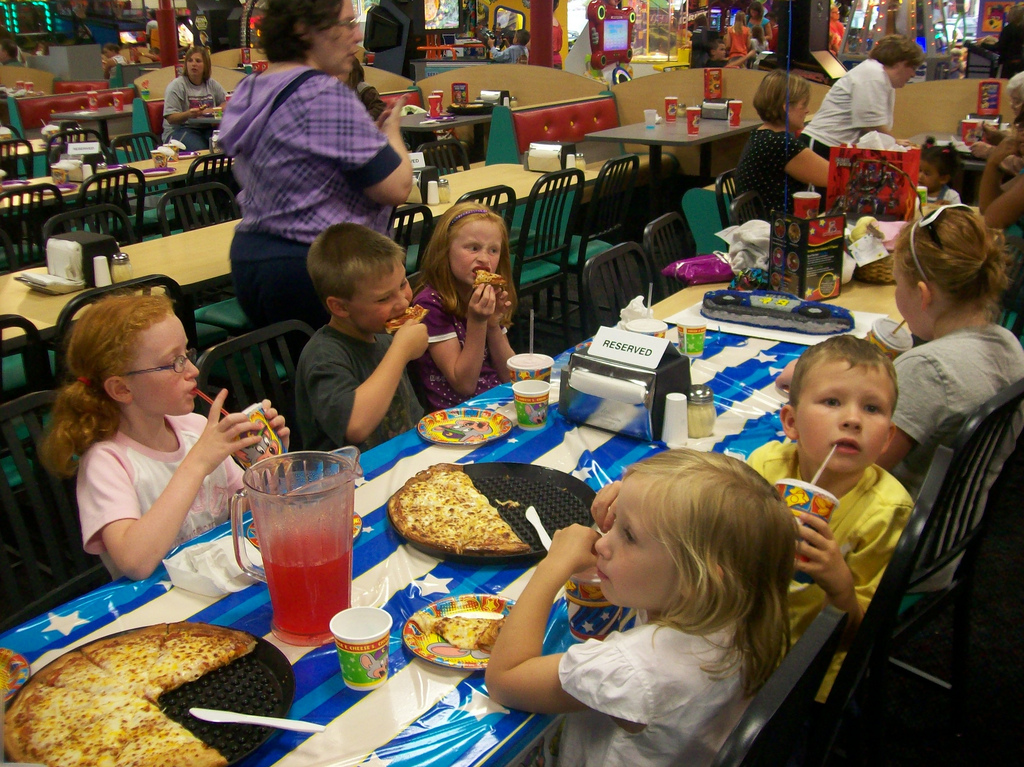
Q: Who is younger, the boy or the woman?
A: The boy is younger than the woman.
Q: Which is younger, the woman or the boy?
A: The boy is younger than the woman.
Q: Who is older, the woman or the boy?
A: The woman is older than the boy.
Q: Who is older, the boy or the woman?
A: The woman is older than the boy.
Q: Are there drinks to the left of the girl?
A: Yes, there is a drink to the left of the girl.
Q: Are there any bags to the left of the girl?
A: No, there is a drink to the left of the girl.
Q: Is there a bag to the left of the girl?
A: No, there is a drink to the left of the girl.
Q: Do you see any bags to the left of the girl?
A: No, there is a drink to the left of the girl.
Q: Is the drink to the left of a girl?
A: Yes, the drink is to the left of a girl.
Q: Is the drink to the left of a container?
A: No, the drink is to the left of a girl.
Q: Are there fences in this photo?
A: No, there are no fences.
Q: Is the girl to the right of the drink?
A: Yes, the girl is to the right of the drink.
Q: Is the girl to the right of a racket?
A: No, the girl is to the right of the drink.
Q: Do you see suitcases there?
A: No, there are no suitcases.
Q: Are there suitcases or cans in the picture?
A: No, there are no suitcases or cans.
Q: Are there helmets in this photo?
A: No, there are no helmets.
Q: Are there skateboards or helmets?
A: No, there are no helmets or skateboards.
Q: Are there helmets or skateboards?
A: No, there are no helmets or skateboards.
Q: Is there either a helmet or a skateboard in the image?
A: No, there are no helmets or skateboards.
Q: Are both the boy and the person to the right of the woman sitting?
A: Yes, both the boy and the person are sitting.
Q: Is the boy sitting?
A: Yes, the boy is sitting.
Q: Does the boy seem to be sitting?
A: Yes, the boy is sitting.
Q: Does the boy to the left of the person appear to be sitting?
A: Yes, the boy is sitting.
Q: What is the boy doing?
A: The boy is sitting.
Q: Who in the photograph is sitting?
A: The boy is sitting.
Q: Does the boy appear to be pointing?
A: No, the boy is sitting.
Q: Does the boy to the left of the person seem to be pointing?
A: No, the boy is sitting.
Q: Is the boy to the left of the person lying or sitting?
A: The boy is sitting.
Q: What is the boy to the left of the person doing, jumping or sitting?
A: The boy is sitting.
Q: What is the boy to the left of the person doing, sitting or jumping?
A: The boy is sitting.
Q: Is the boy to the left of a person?
A: Yes, the boy is to the left of a person.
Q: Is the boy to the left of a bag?
A: No, the boy is to the left of a person.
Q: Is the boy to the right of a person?
A: No, the boy is to the left of a person.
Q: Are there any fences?
A: No, there are no fences.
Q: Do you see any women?
A: Yes, there is a woman.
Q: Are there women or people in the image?
A: Yes, there is a woman.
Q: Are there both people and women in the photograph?
A: Yes, there are both a woman and a person.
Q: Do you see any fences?
A: No, there are no fences.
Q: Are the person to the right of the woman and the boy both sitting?
A: Yes, both the person and the boy are sitting.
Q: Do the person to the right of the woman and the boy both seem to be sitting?
A: Yes, both the person and the boy are sitting.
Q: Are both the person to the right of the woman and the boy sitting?
A: Yes, both the person and the boy are sitting.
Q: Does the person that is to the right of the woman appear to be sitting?
A: Yes, the person is sitting.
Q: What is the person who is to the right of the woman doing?
A: The person is sitting.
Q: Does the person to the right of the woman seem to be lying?
A: No, the person is sitting.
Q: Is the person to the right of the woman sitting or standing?
A: The person is sitting.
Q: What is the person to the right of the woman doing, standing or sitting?
A: The person is sitting.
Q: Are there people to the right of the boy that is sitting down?
A: Yes, there is a person to the right of the boy.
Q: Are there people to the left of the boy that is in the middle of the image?
A: No, the person is to the right of the boy.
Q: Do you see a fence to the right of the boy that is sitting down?
A: No, there is a person to the right of the boy.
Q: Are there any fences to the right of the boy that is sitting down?
A: No, there is a person to the right of the boy.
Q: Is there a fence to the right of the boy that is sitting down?
A: No, there is a person to the right of the boy.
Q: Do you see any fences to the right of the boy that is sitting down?
A: No, there is a person to the right of the boy.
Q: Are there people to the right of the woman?
A: Yes, there is a person to the right of the woman.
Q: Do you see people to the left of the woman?
A: No, the person is to the right of the woman.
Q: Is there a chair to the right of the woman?
A: No, there is a person to the right of the woman.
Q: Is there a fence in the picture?
A: No, there are no fences.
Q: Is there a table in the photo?
A: Yes, there is a table.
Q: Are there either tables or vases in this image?
A: Yes, there is a table.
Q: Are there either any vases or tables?
A: Yes, there is a table.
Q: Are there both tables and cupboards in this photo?
A: No, there is a table but no cupboards.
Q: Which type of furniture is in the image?
A: The furniture is a table.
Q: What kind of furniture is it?
A: The piece of furniture is a table.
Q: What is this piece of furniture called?
A: This is a table.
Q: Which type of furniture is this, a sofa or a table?
A: This is a table.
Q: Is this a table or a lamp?
A: This is a table.